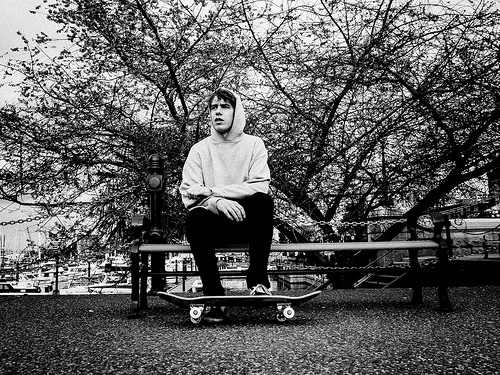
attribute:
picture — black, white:
[7, 10, 481, 368]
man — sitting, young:
[166, 70, 291, 287]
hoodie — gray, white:
[196, 129, 263, 186]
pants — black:
[185, 214, 277, 278]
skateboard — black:
[154, 283, 324, 308]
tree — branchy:
[67, 33, 148, 99]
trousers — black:
[203, 226, 274, 260]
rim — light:
[167, 292, 185, 305]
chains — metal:
[297, 214, 408, 228]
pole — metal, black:
[144, 170, 166, 232]